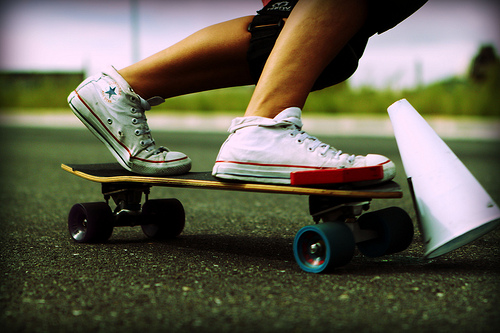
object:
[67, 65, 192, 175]
shoe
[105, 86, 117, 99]
star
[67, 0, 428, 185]
person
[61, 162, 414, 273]
skateboard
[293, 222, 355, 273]
wheel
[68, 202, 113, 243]
wheels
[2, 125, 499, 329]
concrete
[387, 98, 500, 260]
cone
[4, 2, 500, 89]
sky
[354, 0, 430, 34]
shorts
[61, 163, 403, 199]
trim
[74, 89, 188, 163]
line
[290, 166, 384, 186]
object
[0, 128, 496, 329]
street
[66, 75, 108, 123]
left foot heel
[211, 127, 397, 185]
foot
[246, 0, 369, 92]
knee brace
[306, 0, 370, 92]
left knee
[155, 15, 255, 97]
legs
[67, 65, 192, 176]
foot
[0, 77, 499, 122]
grass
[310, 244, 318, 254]
screw